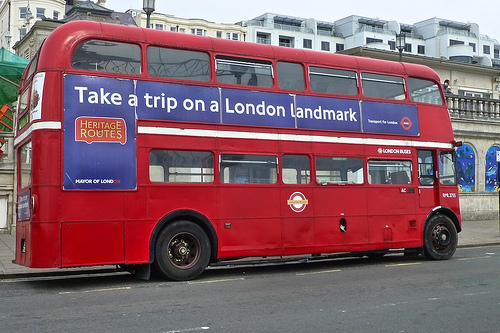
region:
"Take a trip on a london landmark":
[71, 83, 367, 121]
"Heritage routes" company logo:
[72, 112, 135, 148]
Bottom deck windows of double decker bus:
[141, 142, 463, 194]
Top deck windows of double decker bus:
[61, 35, 452, 105]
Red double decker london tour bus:
[13, 12, 479, 277]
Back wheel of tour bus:
[138, 212, 230, 283]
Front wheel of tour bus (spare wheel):
[416, 207, 476, 267]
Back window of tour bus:
[14, 140, 41, 190]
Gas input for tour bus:
[335, 216, 352, 236]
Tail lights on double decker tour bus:
[7, 195, 38, 215]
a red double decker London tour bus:
[13, 7, 490, 322]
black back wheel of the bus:
[139, 205, 220, 285]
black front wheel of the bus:
[414, 207, 465, 264]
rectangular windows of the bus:
[143, 143, 425, 187]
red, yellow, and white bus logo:
[281, 187, 314, 219]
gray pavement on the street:
[258, 277, 484, 324]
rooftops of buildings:
[248, 7, 492, 50]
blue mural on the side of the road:
[457, 140, 482, 197]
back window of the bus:
[16, 149, 34, 186]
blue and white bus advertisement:
[66, 71, 414, 125]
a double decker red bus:
[14, 21, 464, 284]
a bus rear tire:
[152, 215, 212, 284]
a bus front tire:
[423, 210, 458, 260]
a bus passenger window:
[70, 37, 140, 73]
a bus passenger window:
[144, 44, 210, 79]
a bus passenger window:
[211, 54, 271, 91]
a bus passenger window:
[275, 60, 305, 89]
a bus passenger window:
[306, 64, 356, 95]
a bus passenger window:
[359, 69, 404, 97]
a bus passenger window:
[404, 74, 441, 106]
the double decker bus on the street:
[14, 18, 469, 263]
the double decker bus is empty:
[16, 25, 499, 287]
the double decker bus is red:
[18, 17, 468, 267]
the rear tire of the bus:
[151, 214, 213, 286]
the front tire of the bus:
[383, 202, 467, 259]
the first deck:
[43, 126, 450, 211]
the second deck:
[65, 37, 463, 111]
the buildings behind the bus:
[22, 5, 498, 245]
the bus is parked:
[17, 19, 461, 313]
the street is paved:
[266, 295, 455, 329]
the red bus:
[9, 21, 471, 281]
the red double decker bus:
[7, 24, 472, 273]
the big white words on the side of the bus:
[71, 79, 361, 127]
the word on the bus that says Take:
[73, 82, 123, 106]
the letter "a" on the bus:
[124, 92, 141, 107]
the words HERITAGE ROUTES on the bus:
[76, 113, 126, 145]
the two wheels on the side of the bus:
[158, 212, 461, 272]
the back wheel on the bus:
[157, 217, 210, 279]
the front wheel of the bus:
[424, 208, 459, 261]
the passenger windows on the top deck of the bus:
[61, 35, 449, 111]